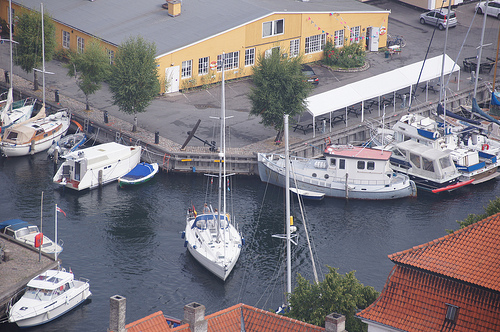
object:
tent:
[300, 54, 461, 118]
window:
[182, 59, 193, 80]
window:
[198, 56, 210, 75]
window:
[217, 50, 240, 72]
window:
[244, 47, 255, 67]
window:
[290, 38, 301, 58]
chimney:
[167, 0, 182, 16]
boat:
[256, 144, 417, 201]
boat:
[0, 105, 71, 157]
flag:
[57, 207, 67, 217]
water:
[98, 221, 179, 276]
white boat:
[60, 135, 145, 193]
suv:
[419, 7, 457, 30]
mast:
[217, 60, 224, 240]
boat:
[118, 162, 160, 190]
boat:
[182, 50, 243, 282]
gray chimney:
[181, 301, 207, 332]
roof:
[122, 302, 333, 332]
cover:
[121, 162, 154, 178]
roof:
[322, 144, 392, 161]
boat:
[288, 187, 326, 201]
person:
[191, 205, 198, 219]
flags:
[317, 27, 321, 31]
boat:
[8, 268, 93, 327]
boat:
[351, 138, 477, 193]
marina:
[1, 87, 498, 332]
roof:
[357, 212, 497, 332]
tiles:
[398, 289, 423, 309]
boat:
[0, 219, 63, 261]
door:
[164, 65, 180, 94]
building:
[0, 0, 390, 94]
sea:
[1, 149, 499, 330]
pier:
[0, 79, 497, 179]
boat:
[45, 132, 86, 164]